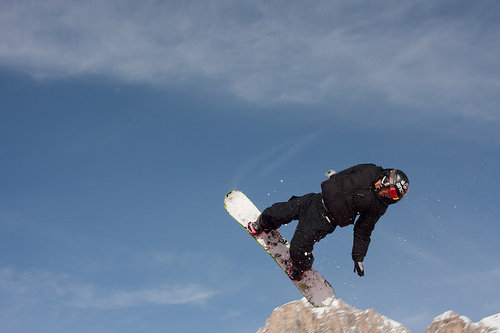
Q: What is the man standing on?
A: A snowboard.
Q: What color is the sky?
A: Blue.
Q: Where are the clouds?
A: In the sky.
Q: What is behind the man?
A: A mountain.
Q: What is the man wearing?
A: Black clothes.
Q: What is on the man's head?
A: A helmet.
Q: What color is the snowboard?
A: White.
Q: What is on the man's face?
A: Goggles.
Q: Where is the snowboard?
A: On the man's feet.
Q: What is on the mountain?
A: Snow.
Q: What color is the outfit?
A: Black.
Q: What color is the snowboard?
A: White.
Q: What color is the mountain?
A: Brown.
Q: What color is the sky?
A: Blue.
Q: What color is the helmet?
A: Black.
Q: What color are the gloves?
A: Black.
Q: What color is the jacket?
A: Black.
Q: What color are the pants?
A: Black.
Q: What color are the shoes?
A: Black.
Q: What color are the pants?
A: Black.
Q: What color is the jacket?
A: Black.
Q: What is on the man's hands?
A: Gloves.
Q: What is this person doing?
A: Snowboarding.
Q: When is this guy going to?
A: Down the mountain.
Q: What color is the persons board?
A: White.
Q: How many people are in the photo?
A: One.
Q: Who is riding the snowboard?
A: The man.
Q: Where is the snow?
A: Under him.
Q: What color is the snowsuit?
A: Black.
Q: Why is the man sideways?
A: He is doing a stunt.